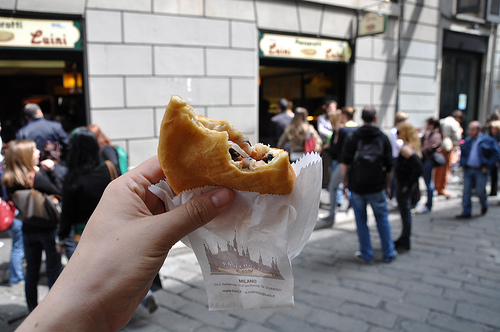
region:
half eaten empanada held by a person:
[150, 83, 325, 214]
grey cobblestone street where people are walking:
[330, 265, 497, 320]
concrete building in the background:
[89, 10, 263, 100]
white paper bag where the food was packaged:
[178, 234, 320, 314]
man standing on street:
[326, 100, 400, 274]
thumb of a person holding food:
[172, 182, 242, 222]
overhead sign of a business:
[243, 29, 366, 66]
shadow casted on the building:
[383, 0, 422, 110]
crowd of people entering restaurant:
[2, 93, 117, 285]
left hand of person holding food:
[13, 172, 186, 327]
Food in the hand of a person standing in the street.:
[157, 93, 300, 242]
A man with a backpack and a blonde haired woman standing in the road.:
[339, 103, 421, 262]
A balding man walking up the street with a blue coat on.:
[454, 117, 498, 218]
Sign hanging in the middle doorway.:
[257, 31, 357, 66]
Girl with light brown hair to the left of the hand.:
[2, 135, 68, 310]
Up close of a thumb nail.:
[208, 184, 233, 210]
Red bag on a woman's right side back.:
[302, 128, 318, 153]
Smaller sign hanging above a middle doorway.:
[356, 9, 385, 39]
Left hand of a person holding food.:
[40, 151, 237, 330]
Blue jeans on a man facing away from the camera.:
[346, 187, 398, 261]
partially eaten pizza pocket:
[161, 95, 296, 195]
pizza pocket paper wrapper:
[142, 151, 322, 309]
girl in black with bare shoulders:
[393, 120, 422, 258]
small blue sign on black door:
[457, 92, 466, 111]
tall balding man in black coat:
[14, 101, 68, 153]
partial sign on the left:
[3, 16, 81, 49]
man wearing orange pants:
[436, 109, 462, 199]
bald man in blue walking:
[461, 120, 497, 224]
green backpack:
[116, 145, 130, 173]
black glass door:
[442, 31, 486, 137]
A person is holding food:
[46, 91, 335, 330]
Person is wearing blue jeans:
[328, 103, 401, 267]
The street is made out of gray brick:
[333, 265, 459, 325]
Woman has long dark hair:
[55, 125, 110, 201]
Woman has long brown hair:
[0, 130, 61, 270]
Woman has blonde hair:
[395, 116, 426, 251]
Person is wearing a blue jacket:
[458, 116, 493, 173]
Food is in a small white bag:
[151, 84, 329, 311]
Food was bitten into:
[136, 91, 338, 232]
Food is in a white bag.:
[153, 89, 295, 326]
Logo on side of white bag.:
[210, 216, 287, 319]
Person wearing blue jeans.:
[343, 193, 420, 276]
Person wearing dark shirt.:
[343, 129, 395, 194]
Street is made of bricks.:
[319, 237, 474, 326]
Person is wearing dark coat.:
[18, 108, 75, 153]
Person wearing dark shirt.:
[398, 135, 444, 224]